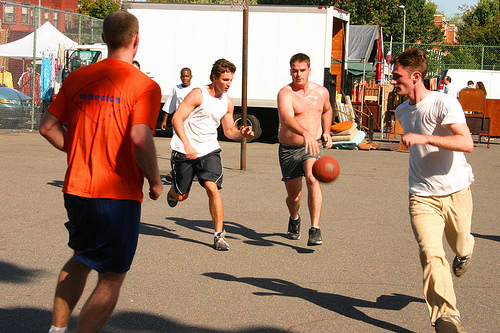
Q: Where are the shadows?
A: On ground.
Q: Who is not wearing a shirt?
A: A man.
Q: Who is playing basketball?
A: The men.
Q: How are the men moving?
A: They are running.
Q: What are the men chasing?
A: Ball.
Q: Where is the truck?
A: Background.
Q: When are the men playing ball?
A: Warm day.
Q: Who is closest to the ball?
A: Shirtless man.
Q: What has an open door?
A: Truck.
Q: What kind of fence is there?
A: Chain link.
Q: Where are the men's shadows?
A: Ground.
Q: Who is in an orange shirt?
A: Man on left.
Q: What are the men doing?
A: Playing basketball.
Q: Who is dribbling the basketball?
A: The man without a shirt.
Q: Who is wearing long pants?
A: The man on the right.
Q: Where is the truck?
A: Parked by the fence.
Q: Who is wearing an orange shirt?
A: The man on the left.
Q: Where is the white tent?
A: On the left behind the fence.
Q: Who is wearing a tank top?
A: The man to the left of the shirtless man.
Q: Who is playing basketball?
A: Five men.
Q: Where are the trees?
A: Behind the fence.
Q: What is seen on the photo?
A: Men.